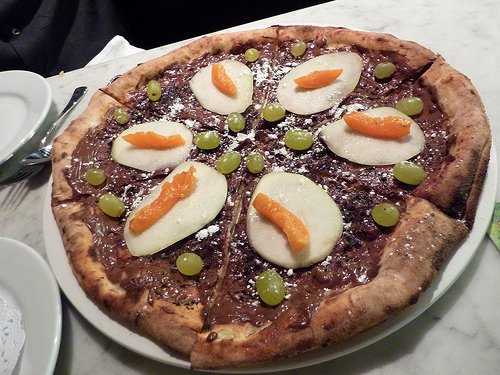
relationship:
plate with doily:
[1, 237, 64, 375] [1, 295, 27, 374]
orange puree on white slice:
[251, 194, 309, 251] [247, 168, 342, 269]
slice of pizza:
[247, 21, 443, 165] [50, 23, 499, 356]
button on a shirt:
[10, 28, 23, 38] [1, 4, 141, 75]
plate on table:
[1, 237, 64, 375] [1, 0, 497, 374]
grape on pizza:
[371, 59, 397, 81] [50, 23, 499, 356]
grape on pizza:
[394, 94, 425, 120] [50, 23, 499, 356]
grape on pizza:
[387, 162, 427, 190] [50, 23, 499, 356]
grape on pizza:
[367, 199, 401, 230] [50, 23, 499, 356]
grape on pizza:
[254, 269, 283, 312] [50, 23, 499, 356]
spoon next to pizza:
[22, 74, 121, 159] [50, 23, 499, 356]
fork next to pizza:
[3, 84, 88, 182] [50, 23, 499, 356]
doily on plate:
[1, 295, 27, 374] [1, 237, 64, 375]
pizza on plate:
[50, 23, 499, 356] [43, 24, 497, 373]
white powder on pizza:
[248, 55, 297, 89] [50, 23, 499, 356]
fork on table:
[3, 84, 88, 182] [1, 0, 497, 374]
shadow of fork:
[4, 175, 30, 216] [3, 84, 88, 182]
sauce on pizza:
[69, 39, 456, 331] [50, 23, 499, 356]